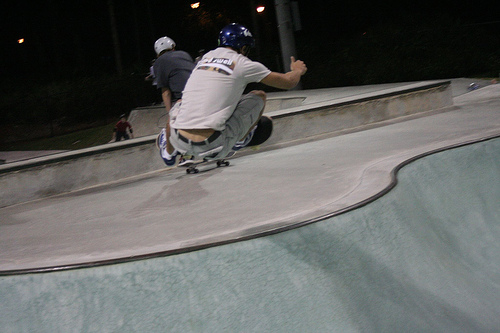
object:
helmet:
[219, 21, 256, 47]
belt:
[173, 129, 222, 148]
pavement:
[0, 77, 500, 278]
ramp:
[0, 135, 500, 333]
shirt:
[167, 46, 278, 133]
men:
[112, 113, 135, 142]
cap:
[151, 37, 177, 55]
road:
[0, 84, 500, 277]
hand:
[287, 55, 307, 76]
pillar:
[274, 1, 300, 91]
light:
[255, 4, 269, 14]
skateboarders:
[151, 36, 199, 115]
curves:
[324, 157, 388, 205]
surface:
[0, 136, 500, 332]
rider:
[0, 80, 453, 210]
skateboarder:
[155, 22, 311, 168]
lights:
[188, 1, 204, 10]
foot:
[156, 127, 179, 166]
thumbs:
[290, 56, 297, 65]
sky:
[0, 0, 500, 92]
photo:
[0, 0, 500, 333]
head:
[218, 23, 253, 53]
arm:
[238, 60, 300, 89]